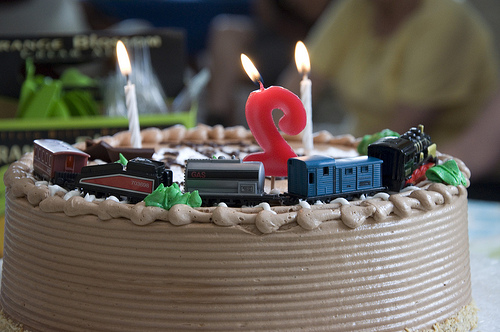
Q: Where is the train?
A: On cake.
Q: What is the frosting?
A: Chocolate.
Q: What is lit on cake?
A: Candles.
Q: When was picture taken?
A: During party.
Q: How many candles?
A: Three.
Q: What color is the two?
A: Red.